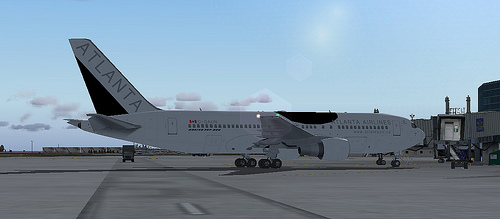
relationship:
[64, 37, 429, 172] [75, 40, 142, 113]
plane has lettering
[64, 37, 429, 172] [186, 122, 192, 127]
plane has window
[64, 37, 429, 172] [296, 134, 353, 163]
plane has engine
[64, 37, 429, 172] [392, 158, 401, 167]
plane has wheel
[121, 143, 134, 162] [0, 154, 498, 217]
truck on tarmac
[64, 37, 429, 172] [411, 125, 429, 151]
plane has a nose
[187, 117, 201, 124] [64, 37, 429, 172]
flag on plane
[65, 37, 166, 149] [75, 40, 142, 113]
tail has lettering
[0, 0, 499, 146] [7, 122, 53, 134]
sky has cloud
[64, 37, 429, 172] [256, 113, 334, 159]
plane has a wing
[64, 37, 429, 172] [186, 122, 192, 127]
plane has a window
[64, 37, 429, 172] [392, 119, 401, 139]
plane has a door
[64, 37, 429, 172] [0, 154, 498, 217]
plane on tarmac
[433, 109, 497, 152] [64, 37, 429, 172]
dock for plane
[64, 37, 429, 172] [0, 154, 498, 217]
plane sits on tarmac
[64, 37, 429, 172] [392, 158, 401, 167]
plane has a wheel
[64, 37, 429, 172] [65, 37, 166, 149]
plane has a tail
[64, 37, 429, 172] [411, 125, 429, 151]
plane has nose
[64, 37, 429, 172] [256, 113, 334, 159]
plane has wing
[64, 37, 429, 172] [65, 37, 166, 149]
plane has tail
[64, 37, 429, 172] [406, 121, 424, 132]
plane has cockpit